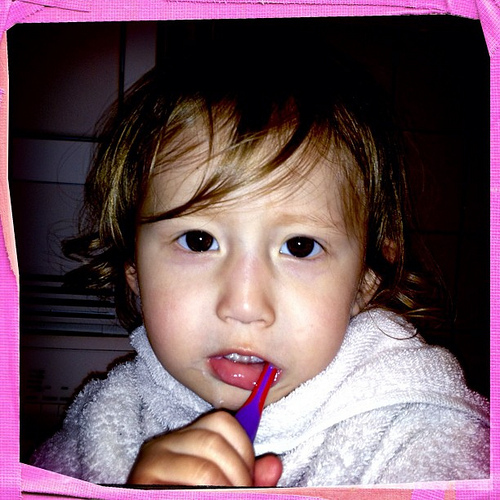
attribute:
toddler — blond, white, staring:
[18, 32, 481, 474]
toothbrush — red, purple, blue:
[227, 350, 286, 449]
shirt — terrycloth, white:
[88, 322, 460, 482]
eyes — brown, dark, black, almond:
[174, 230, 329, 264]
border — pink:
[2, 1, 498, 31]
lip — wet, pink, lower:
[214, 357, 265, 387]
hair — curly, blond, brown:
[95, 63, 430, 318]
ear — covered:
[355, 210, 409, 303]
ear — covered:
[115, 215, 152, 312]